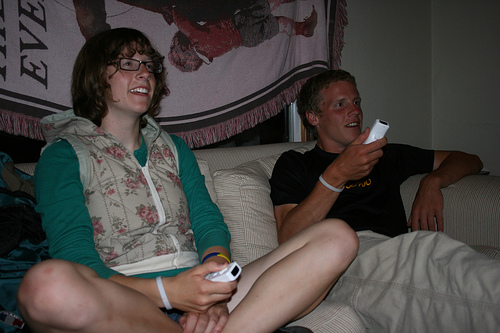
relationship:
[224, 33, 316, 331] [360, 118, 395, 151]
girl holding controller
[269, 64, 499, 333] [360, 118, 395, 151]
boy holding controller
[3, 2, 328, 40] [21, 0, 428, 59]
blanket on wall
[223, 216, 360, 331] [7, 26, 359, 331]
leg on girl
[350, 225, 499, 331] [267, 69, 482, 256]
blanket on boy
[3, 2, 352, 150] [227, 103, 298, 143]
blanket over window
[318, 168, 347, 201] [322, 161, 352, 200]
whiteband on wrist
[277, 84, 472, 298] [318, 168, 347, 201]
boy with whiteband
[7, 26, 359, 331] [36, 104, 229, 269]
girl with jacket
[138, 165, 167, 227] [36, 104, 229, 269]
zipper on jacket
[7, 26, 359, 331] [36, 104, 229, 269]
girl wearing jacket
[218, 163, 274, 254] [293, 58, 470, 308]
pillow back of man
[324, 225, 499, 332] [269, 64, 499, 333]
blanket back of boy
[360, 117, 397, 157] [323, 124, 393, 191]
controller in hand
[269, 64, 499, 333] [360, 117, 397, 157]
boy with controller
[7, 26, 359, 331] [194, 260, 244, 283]
girl with controller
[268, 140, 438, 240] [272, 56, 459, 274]
black shirt on man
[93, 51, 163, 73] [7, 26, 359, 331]
eyeglasses on girl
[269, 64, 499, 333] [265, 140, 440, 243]
boy with t shirt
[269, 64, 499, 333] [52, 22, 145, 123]
boy has hair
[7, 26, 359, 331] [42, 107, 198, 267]
girl has vest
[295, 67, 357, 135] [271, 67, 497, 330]
hair on guy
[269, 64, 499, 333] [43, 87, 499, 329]
boy on couch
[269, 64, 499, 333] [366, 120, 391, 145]
boy holding game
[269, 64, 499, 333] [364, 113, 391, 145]
boy holding wii